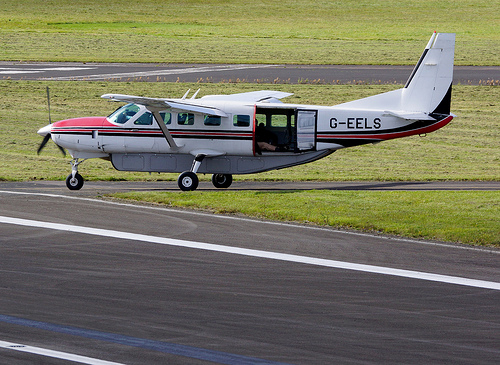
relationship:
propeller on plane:
[30, 56, 58, 164] [38, 24, 468, 185]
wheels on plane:
[37, 164, 237, 200] [38, 24, 468, 185]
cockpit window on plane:
[117, 100, 142, 120] [38, 24, 468, 185]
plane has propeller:
[38, 24, 468, 185] [30, 56, 58, 164]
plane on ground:
[38, 24, 468, 185] [22, 175, 499, 216]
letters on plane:
[305, 102, 396, 138] [38, 24, 468, 185]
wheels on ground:
[37, 164, 237, 200] [22, 175, 499, 216]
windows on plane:
[137, 103, 266, 132] [38, 24, 468, 185]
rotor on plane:
[36, 122, 56, 136] [38, 24, 468, 185]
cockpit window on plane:
[113, 104, 141, 123] [38, 24, 468, 185]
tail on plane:
[393, 31, 460, 151] [38, 24, 468, 185]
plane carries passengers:
[38, 24, 468, 185] [250, 118, 280, 158]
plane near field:
[38, 24, 468, 185] [19, 86, 40, 185]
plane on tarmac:
[38, 24, 468, 185] [20, 207, 462, 364]